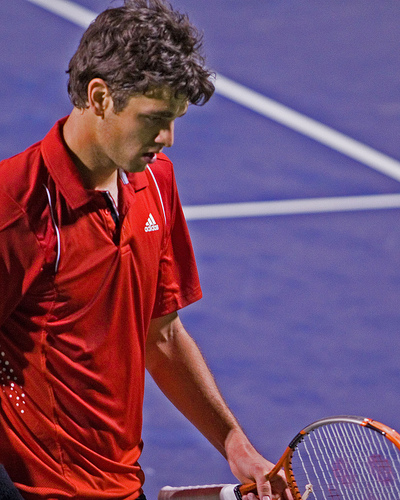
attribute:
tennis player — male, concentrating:
[2, 4, 292, 499]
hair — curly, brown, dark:
[67, 4, 211, 111]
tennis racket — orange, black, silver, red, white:
[158, 409, 397, 500]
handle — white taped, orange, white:
[159, 475, 243, 500]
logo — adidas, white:
[146, 215, 160, 232]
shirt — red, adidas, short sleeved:
[0, 110, 203, 500]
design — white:
[0, 347, 34, 414]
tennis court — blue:
[1, 2, 397, 499]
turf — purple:
[4, 2, 392, 498]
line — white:
[37, 0, 399, 183]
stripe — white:
[36, 173, 70, 275]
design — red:
[330, 448, 393, 489]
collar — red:
[39, 116, 153, 211]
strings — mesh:
[295, 419, 394, 499]